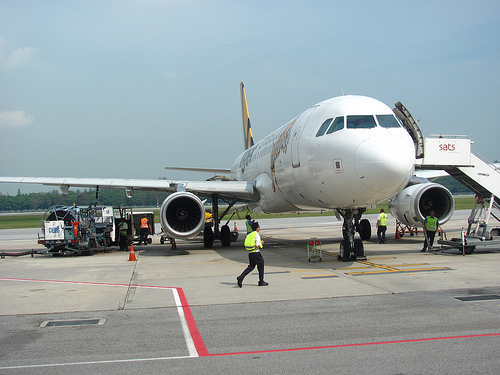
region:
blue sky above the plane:
[101, 57, 161, 122]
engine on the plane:
[163, 185, 213, 245]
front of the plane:
[328, 108, 451, 238]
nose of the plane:
[346, 133, 414, 196]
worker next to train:
[231, 220, 272, 287]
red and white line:
[166, 297, 223, 356]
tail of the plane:
[231, 100, 268, 138]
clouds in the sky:
[12, 41, 61, 135]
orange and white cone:
[122, 241, 141, 268]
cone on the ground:
[108, 240, 146, 284]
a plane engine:
[150, 185, 205, 240]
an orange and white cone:
[127, 244, 136, 261]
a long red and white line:
[168, 283, 207, 358]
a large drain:
[41, 318, 106, 325]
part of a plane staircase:
[423, 130, 498, 201]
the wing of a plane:
[0, 172, 253, 210]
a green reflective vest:
[243, 230, 263, 253]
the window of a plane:
[348, 110, 375, 128]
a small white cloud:
[0, 108, 31, 127]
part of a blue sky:
[287, 0, 497, 74]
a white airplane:
[224, 92, 421, 215]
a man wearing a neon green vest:
[236, 220, 269, 283]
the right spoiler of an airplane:
[6, 171, 247, 196]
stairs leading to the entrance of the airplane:
[420, 130, 495, 192]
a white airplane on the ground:
[266, 85, 406, 260]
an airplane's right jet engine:
[160, 191, 202, 237]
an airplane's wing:
[236, 82, 258, 151]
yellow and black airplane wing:
[236, 81, 256, 143]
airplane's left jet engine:
[412, 178, 451, 218]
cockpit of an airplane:
[324, 116, 401, 130]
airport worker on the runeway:
[236, 215, 270, 290]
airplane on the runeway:
[1, 77, 498, 264]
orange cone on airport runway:
[124, 242, 141, 264]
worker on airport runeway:
[416, 208, 442, 253]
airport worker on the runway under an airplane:
[374, 205, 391, 241]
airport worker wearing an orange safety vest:
[136, 213, 154, 245]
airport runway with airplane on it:
[1, 213, 498, 369]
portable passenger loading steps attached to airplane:
[421, 133, 498, 255]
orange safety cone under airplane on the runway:
[231, 219, 238, 234]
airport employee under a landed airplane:
[244, 211, 251, 231]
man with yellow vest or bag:
[234, 219, 270, 292]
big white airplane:
[0, 78, 498, 256]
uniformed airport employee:
[231, 213, 273, 293]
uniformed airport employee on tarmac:
[411, 208, 442, 254]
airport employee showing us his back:
[371, 207, 393, 246]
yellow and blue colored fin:
[226, 77, 260, 154]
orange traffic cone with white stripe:
[124, 240, 138, 262]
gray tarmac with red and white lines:
[1, 208, 498, 374]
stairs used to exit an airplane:
[423, 132, 498, 249]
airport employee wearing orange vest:
[134, 213, 153, 248]